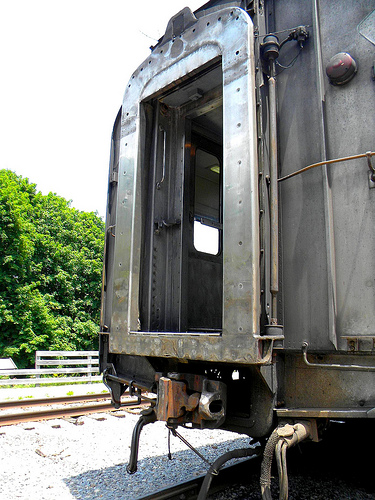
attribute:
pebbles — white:
[1, 407, 274, 499]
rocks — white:
[77, 480, 133, 498]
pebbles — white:
[100, 412, 136, 444]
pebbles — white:
[10, 385, 69, 398]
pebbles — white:
[12, 458, 34, 487]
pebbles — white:
[75, 433, 99, 454]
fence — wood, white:
[1, 346, 101, 386]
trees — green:
[0, 168, 108, 380]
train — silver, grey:
[104, 1, 373, 489]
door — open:
[140, 54, 228, 337]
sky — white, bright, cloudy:
[3, 1, 207, 221]